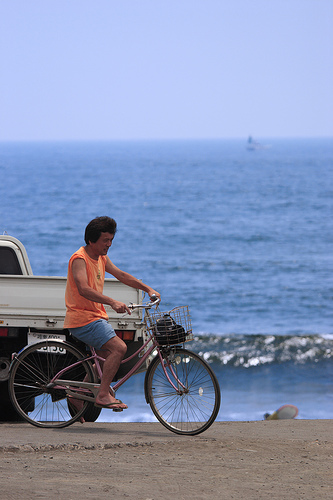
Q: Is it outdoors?
A: Yes, it is outdoors.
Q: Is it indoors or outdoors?
A: It is outdoors.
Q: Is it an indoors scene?
A: No, it is outdoors.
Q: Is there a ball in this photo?
A: No, there are no balls.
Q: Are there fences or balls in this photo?
A: No, there are no balls or fences.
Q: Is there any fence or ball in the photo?
A: No, there are no balls or fences.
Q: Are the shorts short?
A: Yes, the shorts are short.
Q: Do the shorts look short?
A: Yes, the shorts are short.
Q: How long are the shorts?
A: The shorts are short.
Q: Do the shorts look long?
A: No, the shorts are short.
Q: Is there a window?
A: Yes, there is a window.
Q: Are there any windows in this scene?
A: Yes, there is a window.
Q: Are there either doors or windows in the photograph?
A: Yes, there is a window.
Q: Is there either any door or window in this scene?
A: Yes, there is a window.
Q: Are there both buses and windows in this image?
A: No, there is a window but no buses.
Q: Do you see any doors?
A: No, there are no doors.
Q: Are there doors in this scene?
A: No, there are no doors.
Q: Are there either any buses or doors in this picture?
A: No, there are no doors or buses.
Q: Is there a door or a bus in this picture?
A: No, there are no doors or buses.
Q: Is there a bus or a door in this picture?
A: No, there are no doors or buses.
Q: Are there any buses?
A: No, there are no buses.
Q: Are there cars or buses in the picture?
A: No, there are no buses or cars.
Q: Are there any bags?
A: Yes, there is a bag.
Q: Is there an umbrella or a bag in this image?
A: Yes, there is a bag.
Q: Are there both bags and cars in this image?
A: No, there is a bag but no cars.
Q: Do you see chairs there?
A: No, there are no chairs.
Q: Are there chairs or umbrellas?
A: No, there are no chairs or umbrellas.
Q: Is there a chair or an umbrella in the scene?
A: No, there are no chairs or umbrellas.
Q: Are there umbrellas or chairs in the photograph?
A: No, there are no chairs or umbrellas.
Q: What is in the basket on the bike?
A: The bag is in the basket.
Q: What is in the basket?
A: The bag is in the basket.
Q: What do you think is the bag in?
A: The bag is in the basket.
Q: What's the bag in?
A: The bag is in the basket.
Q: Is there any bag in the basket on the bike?
A: Yes, there is a bag in the basket.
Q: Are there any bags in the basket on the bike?
A: Yes, there is a bag in the basket.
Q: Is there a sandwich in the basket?
A: No, there is a bag in the basket.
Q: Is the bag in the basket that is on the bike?
A: Yes, the bag is in the basket.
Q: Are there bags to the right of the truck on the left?
A: Yes, there is a bag to the right of the truck.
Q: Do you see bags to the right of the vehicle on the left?
A: Yes, there is a bag to the right of the truck.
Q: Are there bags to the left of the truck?
A: No, the bag is to the right of the truck.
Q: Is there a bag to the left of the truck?
A: No, the bag is to the right of the truck.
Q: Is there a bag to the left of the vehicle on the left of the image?
A: No, the bag is to the right of the truck.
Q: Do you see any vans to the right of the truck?
A: No, there is a bag to the right of the truck.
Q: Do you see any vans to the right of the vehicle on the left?
A: No, there is a bag to the right of the truck.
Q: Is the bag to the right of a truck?
A: Yes, the bag is to the right of a truck.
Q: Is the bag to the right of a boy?
A: No, the bag is to the right of a truck.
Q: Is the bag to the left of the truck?
A: No, the bag is to the right of the truck.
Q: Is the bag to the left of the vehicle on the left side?
A: No, the bag is to the right of the truck.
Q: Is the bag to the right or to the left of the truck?
A: The bag is to the right of the truck.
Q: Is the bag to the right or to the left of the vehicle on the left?
A: The bag is to the right of the truck.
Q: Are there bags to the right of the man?
A: Yes, there is a bag to the right of the man.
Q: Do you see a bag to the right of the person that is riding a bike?
A: Yes, there is a bag to the right of the man.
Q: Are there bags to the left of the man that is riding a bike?
A: No, the bag is to the right of the man.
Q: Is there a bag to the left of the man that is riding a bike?
A: No, the bag is to the right of the man.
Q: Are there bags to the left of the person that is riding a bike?
A: No, the bag is to the right of the man.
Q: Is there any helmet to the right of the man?
A: No, there is a bag to the right of the man.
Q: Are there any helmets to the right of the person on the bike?
A: No, there is a bag to the right of the man.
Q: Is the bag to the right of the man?
A: Yes, the bag is to the right of the man.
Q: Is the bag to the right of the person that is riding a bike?
A: Yes, the bag is to the right of the man.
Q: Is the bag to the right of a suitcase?
A: No, the bag is to the right of the man.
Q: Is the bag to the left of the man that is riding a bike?
A: No, the bag is to the right of the man.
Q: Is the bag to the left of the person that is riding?
A: No, the bag is to the right of the man.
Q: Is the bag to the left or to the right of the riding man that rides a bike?
A: The bag is to the right of the man.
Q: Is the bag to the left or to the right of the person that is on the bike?
A: The bag is to the right of the man.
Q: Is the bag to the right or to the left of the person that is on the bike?
A: The bag is to the right of the man.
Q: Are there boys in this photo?
A: No, there are no boys.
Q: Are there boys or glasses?
A: No, there are no boys or glasses.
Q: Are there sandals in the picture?
A: Yes, there are sandals.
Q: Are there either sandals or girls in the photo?
A: Yes, there are sandals.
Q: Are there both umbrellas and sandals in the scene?
A: No, there are sandals but no umbrellas.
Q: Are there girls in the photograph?
A: No, there are no girls.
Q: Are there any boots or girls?
A: No, there are no girls or boots.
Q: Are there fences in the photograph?
A: No, there are no fences.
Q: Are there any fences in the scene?
A: No, there are no fences.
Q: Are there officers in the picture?
A: No, there are no officers.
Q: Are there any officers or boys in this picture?
A: No, there are no officers or boys.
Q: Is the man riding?
A: Yes, the man is riding.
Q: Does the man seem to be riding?
A: Yes, the man is riding.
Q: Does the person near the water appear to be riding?
A: Yes, the man is riding.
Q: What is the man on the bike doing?
A: The man is riding.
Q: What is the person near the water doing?
A: The man is riding.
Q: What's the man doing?
A: The man is riding.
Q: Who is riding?
A: The man is riding.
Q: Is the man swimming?
A: No, the man is riding.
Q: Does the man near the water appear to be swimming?
A: No, the man is riding.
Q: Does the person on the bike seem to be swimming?
A: No, the man is riding.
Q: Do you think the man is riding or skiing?
A: The man is riding.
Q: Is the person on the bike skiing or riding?
A: The man is riding.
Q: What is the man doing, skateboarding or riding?
A: The man is riding.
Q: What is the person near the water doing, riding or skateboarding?
A: The man is riding.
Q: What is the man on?
A: The man is on the bike.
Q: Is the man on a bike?
A: Yes, the man is on a bike.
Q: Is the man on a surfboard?
A: No, the man is on a bike.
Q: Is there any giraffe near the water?
A: No, there is a man near the water.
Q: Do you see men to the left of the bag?
A: Yes, there is a man to the left of the bag.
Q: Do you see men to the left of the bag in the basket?
A: Yes, there is a man to the left of the bag.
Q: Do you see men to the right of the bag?
A: No, the man is to the left of the bag.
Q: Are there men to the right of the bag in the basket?
A: No, the man is to the left of the bag.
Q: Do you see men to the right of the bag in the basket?
A: No, the man is to the left of the bag.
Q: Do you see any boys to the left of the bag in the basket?
A: No, there is a man to the left of the bag.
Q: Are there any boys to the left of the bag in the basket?
A: No, there is a man to the left of the bag.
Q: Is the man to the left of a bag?
A: Yes, the man is to the left of a bag.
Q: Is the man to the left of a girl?
A: No, the man is to the left of a bag.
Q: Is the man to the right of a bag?
A: No, the man is to the left of a bag.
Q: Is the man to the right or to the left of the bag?
A: The man is to the left of the bag.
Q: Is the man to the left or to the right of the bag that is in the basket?
A: The man is to the left of the bag.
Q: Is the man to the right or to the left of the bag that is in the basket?
A: The man is to the left of the bag.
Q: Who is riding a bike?
A: The man is riding a bike.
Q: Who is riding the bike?
A: The man is riding a bike.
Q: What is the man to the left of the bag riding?
A: The man is riding a bike.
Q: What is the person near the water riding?
A: The man is riding a bike.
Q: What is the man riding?
A: The man is riding a bike.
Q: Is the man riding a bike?
A: Yes, the man is riding a bike.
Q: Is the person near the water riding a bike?
A: Yes, the man is riding a bike.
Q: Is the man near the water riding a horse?
A: No, the man is riding a bike.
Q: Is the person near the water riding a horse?
A: No, the man is riding a bike.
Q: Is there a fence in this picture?
A: No, there are no fences.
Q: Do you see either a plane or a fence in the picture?
A: No, there are no fences or airplanes.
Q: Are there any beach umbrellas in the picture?
A: No, there are no beach umbrellas.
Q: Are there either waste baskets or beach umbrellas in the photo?
A: No, there are no beach umbrellas or waste baskets.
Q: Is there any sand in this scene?
A: Yes, there is sand.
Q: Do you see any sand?
A: Yes, there is sand.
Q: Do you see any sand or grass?
A: Yes, there is sand.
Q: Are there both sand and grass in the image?
A: No, there is sand but no grass.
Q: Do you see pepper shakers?
A: No, there are no pepper shakers.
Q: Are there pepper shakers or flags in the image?
A: No, there are no pepper shakers or flags.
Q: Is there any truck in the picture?
A: Yes, there is a truck.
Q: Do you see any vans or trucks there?
A: Yes, there is a truck.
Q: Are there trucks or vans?
A: Yes, there is a truck.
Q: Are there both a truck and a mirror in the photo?
A: No, there is a truck but no mirrors.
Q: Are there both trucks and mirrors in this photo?
A: No, there is a truck but no mirrors.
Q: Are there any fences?
A: No, there are no fences.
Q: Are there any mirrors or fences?
A: No, there are no fences or mirrors.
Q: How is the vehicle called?
A: The vehicle is a truck.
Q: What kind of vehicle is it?
A: The vehicle is a truck.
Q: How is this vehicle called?
A: This is a truck.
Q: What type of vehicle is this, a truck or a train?
A: This is a truck.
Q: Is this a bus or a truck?
A: This is a truck.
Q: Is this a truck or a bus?
A: This is a truck.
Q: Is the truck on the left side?
A: Yes, the truck is on the left of the image.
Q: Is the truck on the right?
A: No, the truck is on the left of the image.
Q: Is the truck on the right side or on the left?
A: The truck is on the left of the image.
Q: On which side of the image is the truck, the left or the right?
A: The truck is on the left of the image.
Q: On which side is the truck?
A: The truck is on the left of the image.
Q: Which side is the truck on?
A: The truck is on the left of the image.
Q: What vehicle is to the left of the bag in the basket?
A: The vehicle is a truck.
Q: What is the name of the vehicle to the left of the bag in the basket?
A: The vehicle is a truck.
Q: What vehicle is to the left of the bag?
A: The vehicle is a truck.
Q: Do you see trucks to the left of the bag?
A: Yes, there is a truck to the left of the bag.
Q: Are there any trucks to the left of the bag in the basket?
A: Yes, there is a truck to the left of the bag.